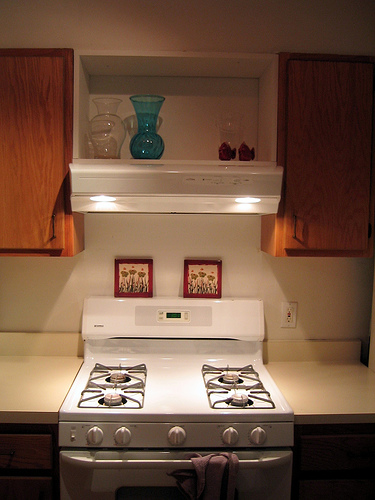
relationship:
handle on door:
[50, 215, 55, 239] [1, 54, 64, 249]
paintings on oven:
[101, 242, 238, 303] [56, 294, 294, 498]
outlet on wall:
[277, 297, 298, 328] [0, 0, 373, 340]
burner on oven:
[200, 364, 263, 389] [56, 294, 294, 498]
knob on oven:
[85, 426, 104, 446] [60, 294, 294, 497]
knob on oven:
[114, 426, 133, 446] [60, 294, 294, 497]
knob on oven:
[165, 426, 187, 446] [60, 294, 294, 497]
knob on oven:
[221, 425, 240, 446] [60, 294, 294, 497]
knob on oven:
[247, 426, 267, 444] [60, 294, 294, 497]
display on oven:
[156, 306, 190, 324] [56, 294, 294, 498]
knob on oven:
[81, 423, 108, 446] [56, 294, 294, 498]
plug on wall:
[274, 297, 303, 333] [3, 216, 373, 339]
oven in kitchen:
[56, 294, 294, 498] [1, 1, 373, 498]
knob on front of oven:
[86, 424, 104, 444] [56, 294, 294, 498]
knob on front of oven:
[112, 425, 133, 446] [56, 294, 294, 498]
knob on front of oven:
[167, 421, 187, 444] [56, 294, 294, 498]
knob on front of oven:
[221, 422, 238, 445] [56, 294, 294, 498]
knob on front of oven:
[247, 425, 266, 443] [56, 294, 294, 498]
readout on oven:
[166, 313, 182, 318] [60, 294, 294, 497]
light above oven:
[91, 194, 120, 201] [56, 294, 294, 498]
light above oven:
[236, 194, 261, 204] [56, 294, 294, 498]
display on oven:
[165, 311, 182, 319] [56, 294, 294, 498]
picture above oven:
[187, 263, 219, 294] [56, 294, 294, 498]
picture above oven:
[118, 263, 149, 294] [56, 294, 294, 498]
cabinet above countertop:
[258, 55, 373, 258] [0, 328, 374, 415]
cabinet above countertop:
[0, 43, 87, 255] [0, 328, 374, 415]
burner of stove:
[86, 362, 148, 387] [88, 322, 324, 428]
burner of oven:
[205, 381, 276, 411] [56, 294, 294, 498]